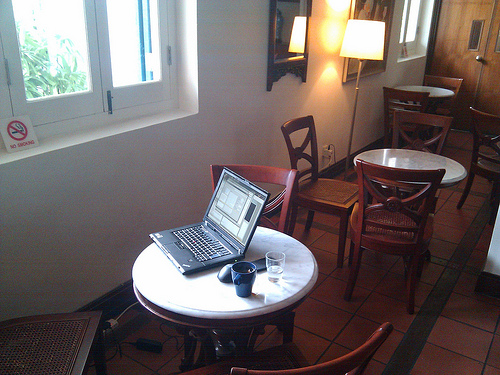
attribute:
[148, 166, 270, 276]
laptop — black, open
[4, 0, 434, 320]
wall — white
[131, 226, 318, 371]
table — white, round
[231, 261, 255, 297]
cup — blue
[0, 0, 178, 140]
window — white